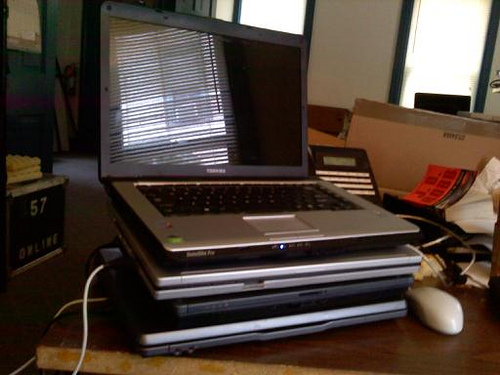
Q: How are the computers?
A: Stacked.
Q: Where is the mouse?
A: On desk.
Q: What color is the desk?
A: Brown.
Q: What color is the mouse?
A: White.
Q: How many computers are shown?
A: Three.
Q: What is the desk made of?
A: Wood.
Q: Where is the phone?
A: Behind computer.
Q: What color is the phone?
A: Black.